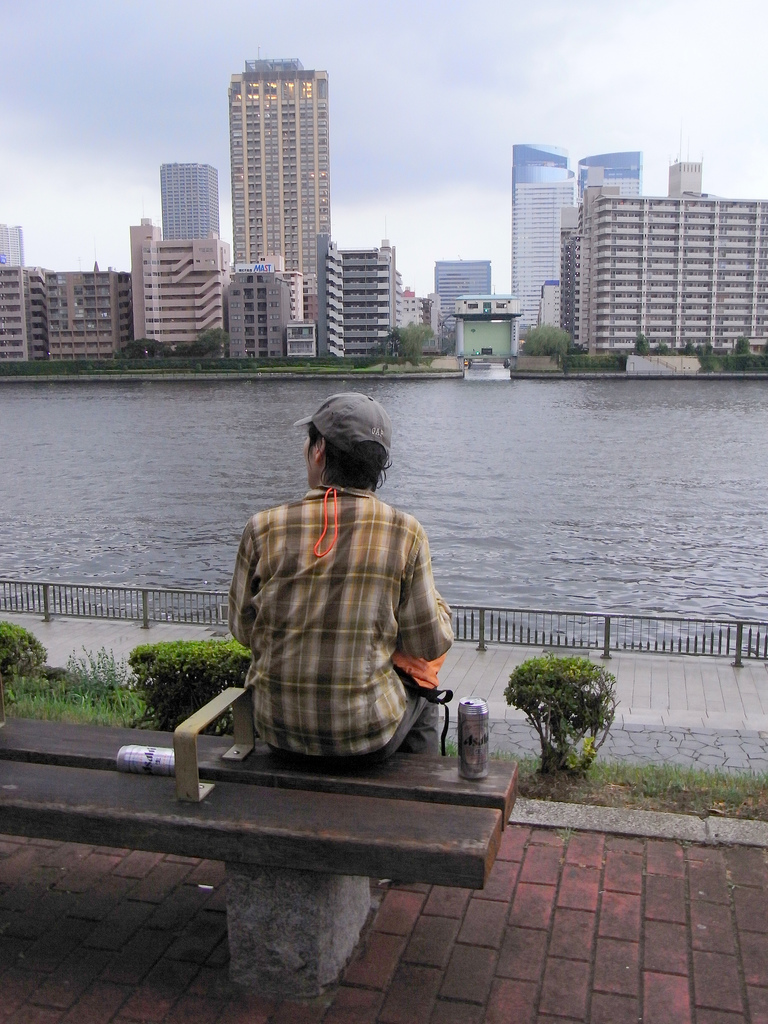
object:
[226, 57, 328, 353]
building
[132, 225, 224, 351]
building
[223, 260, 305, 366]
building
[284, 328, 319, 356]
building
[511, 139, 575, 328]
building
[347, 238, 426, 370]
building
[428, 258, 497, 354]
building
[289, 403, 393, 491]
head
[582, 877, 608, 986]
lines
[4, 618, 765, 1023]
ground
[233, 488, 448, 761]
back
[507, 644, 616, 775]
bush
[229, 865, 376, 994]
part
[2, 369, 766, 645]
water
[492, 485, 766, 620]
waves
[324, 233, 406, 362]
building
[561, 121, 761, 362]
building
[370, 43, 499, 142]
clouds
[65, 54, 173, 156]
clouds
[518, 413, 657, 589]
water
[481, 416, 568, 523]
water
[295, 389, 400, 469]
cap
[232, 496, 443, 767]
shirt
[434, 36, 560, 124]
sky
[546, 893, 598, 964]
brick pavers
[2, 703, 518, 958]
bench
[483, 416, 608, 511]
water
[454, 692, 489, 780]
beer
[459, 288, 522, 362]
building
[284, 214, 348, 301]
wall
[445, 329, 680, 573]
water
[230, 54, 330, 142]
top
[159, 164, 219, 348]
sky scraper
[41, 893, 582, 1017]
walkway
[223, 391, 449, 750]
man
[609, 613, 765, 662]
fence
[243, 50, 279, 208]
wall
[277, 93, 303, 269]
wall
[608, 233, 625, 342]
wall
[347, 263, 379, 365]
wall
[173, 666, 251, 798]
bar